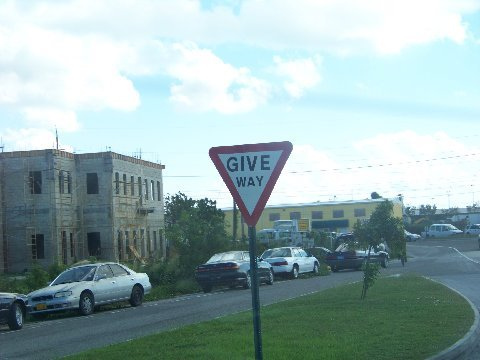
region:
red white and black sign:
[204, 135, 295, 234]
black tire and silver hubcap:
[69, 286, 105, 331]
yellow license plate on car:
[30, 299, 51, 314]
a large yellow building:
[230, 183, 405, 258]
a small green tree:
[312, 196, 431, 318]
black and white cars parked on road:
[193, 239, 323, 300]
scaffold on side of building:
[4, 170, 153, 272]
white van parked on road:
[423, 213, 464, 260]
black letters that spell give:
[221, 149, 274, 170]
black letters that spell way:
[227, 170, 265, 196]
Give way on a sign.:
[197, 137, 296, 222]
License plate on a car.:
[29, 299, 55, 311]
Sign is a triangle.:
[197, 136, 308, 223]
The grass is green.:
[306, 308, 426, 358]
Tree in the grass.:
[351, 205, 406, 294]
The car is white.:
[256, 239, 321, 279]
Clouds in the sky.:
[27, 17, 163, 107]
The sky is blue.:
[355, 67, 470, 123]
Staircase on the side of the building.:
[12, 170, 52, 272]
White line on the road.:
[435, 235, 476, 276]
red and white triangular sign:
[204, 145, 328, 231]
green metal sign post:
[245, 224, 287, 359]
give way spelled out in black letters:
[224, 144, 292, 198]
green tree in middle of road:
[333, 196, 416, 285]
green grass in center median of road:
[291, 292, 411, 356]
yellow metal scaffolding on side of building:
[116, 178, 162, 262]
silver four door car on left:
[25, 254, 172, 328]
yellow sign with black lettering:
[289, 208, 321, 249]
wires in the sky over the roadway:
[375, 143, 468, 178]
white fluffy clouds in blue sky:
[135, 18, 299, 131]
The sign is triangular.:
[198, 135, 303, 222]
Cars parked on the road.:
[173, 233, 399, 287]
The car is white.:
[254, 243, 326, 284]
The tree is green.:
[159, 192, 221, 261]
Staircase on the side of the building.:
[14, 166, 53, 283]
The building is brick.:
[10, 148, 171, 291]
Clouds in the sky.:
[6, 16, 135, 121]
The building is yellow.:
[241, 201, 420, 244]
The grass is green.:
[308, 292, 452, 335]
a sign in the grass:
[209, 140, 301, 358]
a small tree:
[341, 186, 413, 310]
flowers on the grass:
[401, 286, 446, 308]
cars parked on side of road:
[166, 228, 392, 295]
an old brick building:
[1, 144, 159, 266]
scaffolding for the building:
[112, 180, 151, 265]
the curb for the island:
[431, 283, 477, 359]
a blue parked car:
[193, 233, 280, 291]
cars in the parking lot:
[403, 196, 478, 239]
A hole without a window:
[81, 168, 104, 197]